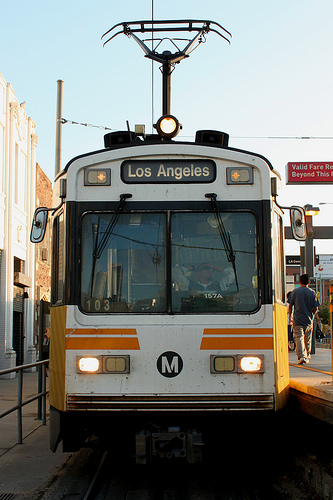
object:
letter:
[154, 350, 182, 380]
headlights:
[77, 354, 101, 376]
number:
[212, 290, 217, 299]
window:
[272, 212, 282, 301]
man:
[286, 273, 321, 366]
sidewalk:
[286, 345, 331, 429]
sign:
[286, 159, 333, 185]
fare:
[309, 164, 324, 172]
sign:
[125, 158, 211, 183]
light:
[82, 168, 110, 184]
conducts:
[101, 18, 233, 65]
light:
[155, 113, 178, 141]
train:
[29, 112, 307, 472]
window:
[80, 210, 168, 317]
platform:
[284, 347, 332, 412]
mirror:
[29, 206, 48, 244]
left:
[3, 172, 57, 403]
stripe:
[288, 360, 331, 379]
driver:
[182, 261, 235, 313]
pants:
[291, 320, 312, 362]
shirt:
[286, 286, 320, 326]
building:
[0, 73, 38, 382]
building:
[34, 162, 54, 363]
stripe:
[61, 325, 141, 335]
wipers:
[205, 193, 240, 295]